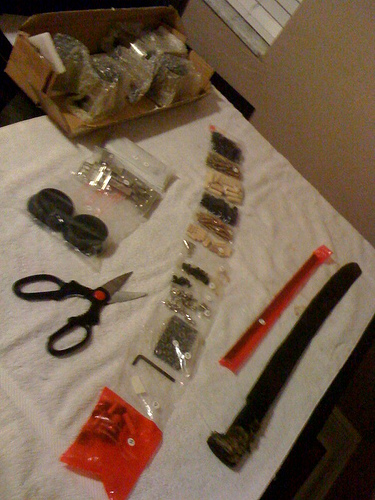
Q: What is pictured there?
A: Supplies.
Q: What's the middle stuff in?
A: Plastic.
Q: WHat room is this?
A: Living room.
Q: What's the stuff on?
A: Towel.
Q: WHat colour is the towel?
A: White.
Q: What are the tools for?
A: Fixing things.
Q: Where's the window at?
A: Back wall.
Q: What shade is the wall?
A: Earth tone.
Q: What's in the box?
A: More stuff.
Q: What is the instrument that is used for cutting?
A: Scissors.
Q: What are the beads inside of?
A: Clear plastic bags.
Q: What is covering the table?
A: A white cloth.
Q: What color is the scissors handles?
A: Black.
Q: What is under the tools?
A: A towel.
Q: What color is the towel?
A: White.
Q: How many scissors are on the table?
A: 1.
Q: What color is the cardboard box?
A: Brown.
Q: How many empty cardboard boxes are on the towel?
A: 0.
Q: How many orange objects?
A: 2.